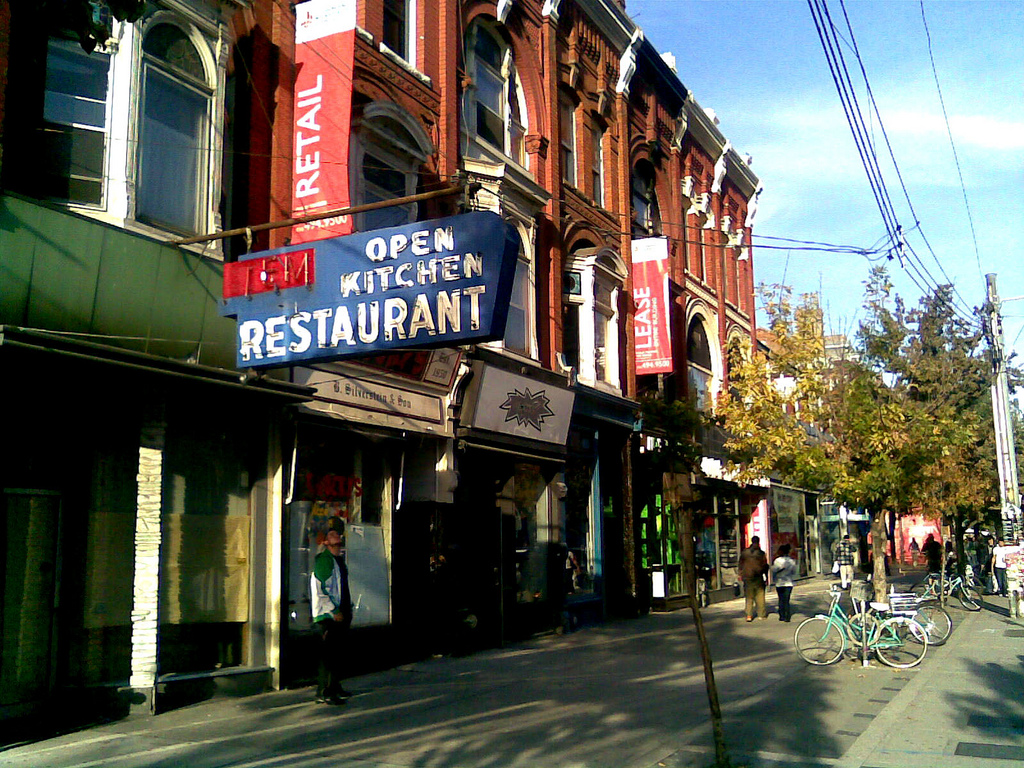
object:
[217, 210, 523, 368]
sign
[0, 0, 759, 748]
building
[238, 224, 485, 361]
word